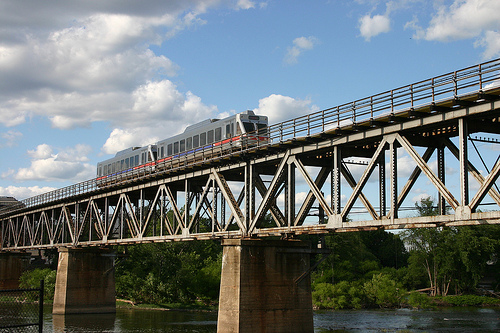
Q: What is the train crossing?
A: Bridge.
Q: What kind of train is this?
A: Electric.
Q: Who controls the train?
A: Conductor.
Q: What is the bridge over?
A: River.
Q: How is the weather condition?
A: Cloudy.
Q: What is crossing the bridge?
A: Trains.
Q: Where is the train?
A: Railroad tracks on a bridge.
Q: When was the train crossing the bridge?
A: Afternoon.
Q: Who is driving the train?
A: An engineer driver.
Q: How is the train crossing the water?
A: On a bridge.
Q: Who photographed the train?
A: A person near the river.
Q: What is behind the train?
A: A train-car.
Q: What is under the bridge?
A: A river.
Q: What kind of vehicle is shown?
A: Train.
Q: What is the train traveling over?
A: Water.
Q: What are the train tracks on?
A: Bridge.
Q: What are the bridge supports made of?
A: Stone.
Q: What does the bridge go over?
A: Water.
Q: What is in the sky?
A: Clouds.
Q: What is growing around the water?
A: Trees.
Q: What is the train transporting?
A: Passengers.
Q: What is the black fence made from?
A: Chain link.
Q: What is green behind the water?
A: Trees.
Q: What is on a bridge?
A: Steel beam.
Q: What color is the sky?
A: Blue.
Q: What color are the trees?
A: Green.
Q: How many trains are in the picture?
A: One.